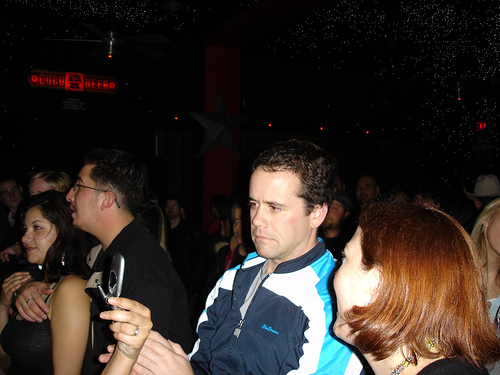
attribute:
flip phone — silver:
[94, 248, 134, 318]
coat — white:
[190, 235, 364, 373]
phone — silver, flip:
[108, 239, 130, 301]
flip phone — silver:
[96, 252, 126, 322]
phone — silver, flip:
[92, 251, 127, 323]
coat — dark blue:
[150, 257, 362, 369]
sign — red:
[26, 70, 117, 92]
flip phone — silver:
[89, 227, 160, 334]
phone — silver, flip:
[96, 251, 128, 310]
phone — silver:
[101, 254, 129, 296]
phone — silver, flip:
[88, 242, 151, 337]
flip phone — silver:
[83, 247, 120, 355]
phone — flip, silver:
[96, 252, 125, 322]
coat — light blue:
[192, 251, 352, 372]